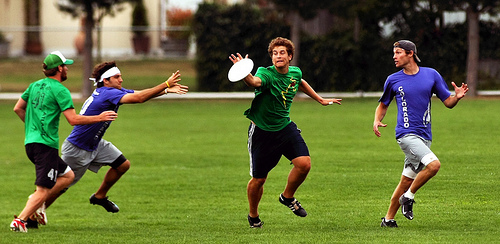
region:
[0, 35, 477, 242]
boys playing with frisbie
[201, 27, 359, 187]
guy reaching for frisbie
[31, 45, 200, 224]
guy diving for frisbie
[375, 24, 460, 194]
man wearing blue shirt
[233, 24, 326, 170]
man wearing green shirt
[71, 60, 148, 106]
guy wearing white head band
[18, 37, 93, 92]
guy wearing green cap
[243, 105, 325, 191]
guy wearing black shorts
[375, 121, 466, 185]
guy wearing grey shorts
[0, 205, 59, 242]
guy wearing red and white sneakers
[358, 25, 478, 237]
This is a person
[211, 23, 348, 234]
This is a person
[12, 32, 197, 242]
This is a person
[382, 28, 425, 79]
Head of a person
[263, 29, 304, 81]
Head of a person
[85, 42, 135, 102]
Head of a person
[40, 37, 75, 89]
Head of a person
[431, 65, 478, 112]
Hand of a person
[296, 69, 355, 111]
Hand of a person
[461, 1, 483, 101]
Trunk of a tree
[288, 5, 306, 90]
Trunk of a tree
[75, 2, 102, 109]
Trunk of a tree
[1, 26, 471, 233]
four people in a field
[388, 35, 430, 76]
a man wearing a cap backwards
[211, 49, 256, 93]
a white frisbee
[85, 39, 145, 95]
a man wearing a white head band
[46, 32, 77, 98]
a man wearing a green and white cap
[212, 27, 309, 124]
a man catching a frisbee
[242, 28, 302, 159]
a man wearing a green shirt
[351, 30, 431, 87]
a man with his head turned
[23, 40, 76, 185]
a mand wearing a green shirt and cap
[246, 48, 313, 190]
a man wearing black shorts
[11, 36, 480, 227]
Four guys playing with a frisbee.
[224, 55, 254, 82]
A white frisbee.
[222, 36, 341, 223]
A guy reaching for the frisbee in front of him.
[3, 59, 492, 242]
The green grass.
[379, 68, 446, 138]
A blue and white short sleeved shirt.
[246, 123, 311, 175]
A pair of navy blue shorts with white stripes down the sides.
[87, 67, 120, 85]
A white bandana.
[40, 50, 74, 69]
A green and white ball cap.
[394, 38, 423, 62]
A grey hat turned around backwards.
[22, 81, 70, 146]
A green short sleeved shirt.